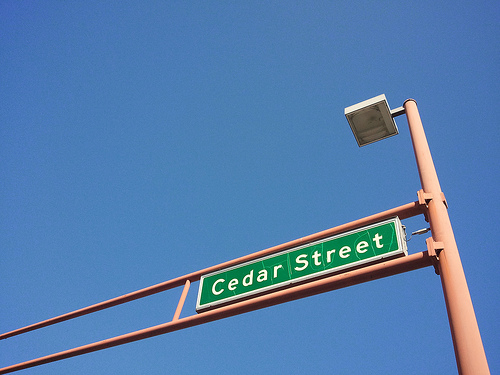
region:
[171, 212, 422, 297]
Cedar Street written on a green sign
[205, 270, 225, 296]
white letter "C" on green street sign.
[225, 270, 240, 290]
white letter "e" on green street sign.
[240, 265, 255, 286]
white letter "d" on green street sign.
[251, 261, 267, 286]
white letter "a" on green street sign.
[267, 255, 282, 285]
white letter "r" on green street sign.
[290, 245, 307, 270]
white letter "S" on green street sign.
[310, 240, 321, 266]
white letter "t" on green street sign.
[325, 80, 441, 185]
light on street lamp post.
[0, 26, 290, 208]
patch of blue sky.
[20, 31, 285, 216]
patch of blue sky on a clear sunny day.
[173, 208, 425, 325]
green sign says Cedar Street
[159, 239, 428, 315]
A green and white rectangle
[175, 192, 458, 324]
A green and white street sign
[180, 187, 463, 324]
A green and white sign on a pole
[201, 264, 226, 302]
A white letter "C"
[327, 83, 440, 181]
A street light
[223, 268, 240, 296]
A white letter "e"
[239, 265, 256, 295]
A white letter "d"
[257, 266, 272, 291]
A white letter "a"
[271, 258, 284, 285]
A white letter "r"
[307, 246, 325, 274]
A white letter "t"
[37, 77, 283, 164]
a clear blue sky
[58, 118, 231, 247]
a sky without clouds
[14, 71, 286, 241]
a lovely pale blue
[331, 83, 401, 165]
a rectangular white light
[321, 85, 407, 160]
a turned off street light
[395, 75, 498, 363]
a red metal pole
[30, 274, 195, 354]
a few pieces of metal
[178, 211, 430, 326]
a green street sign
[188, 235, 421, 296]
large white lower case letters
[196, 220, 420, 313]
the name of a street